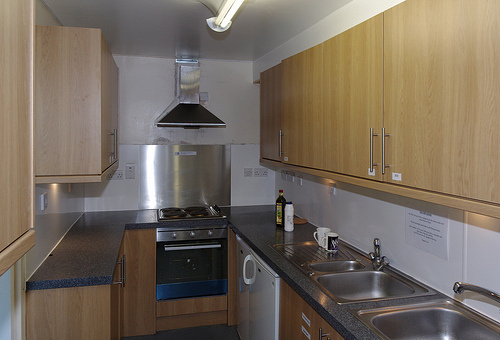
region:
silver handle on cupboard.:
[379, 127, 391, 172]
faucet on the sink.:
[348, 249, 390, 282]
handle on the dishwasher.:
[242, 253, 253, 284]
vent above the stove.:
[154, 101, 221, 138]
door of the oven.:
[163, 242, 223, 277]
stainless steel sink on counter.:
[342, 273, 384, 297]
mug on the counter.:
[312, 231, 340, 248]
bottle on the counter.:
[269, 188, 286, 228]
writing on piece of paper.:
[403, 211, 443, 251]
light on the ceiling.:
[212, 7, 251, 28]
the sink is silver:
[274, 167, 414, 336]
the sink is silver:
[215, 107, 375, 315]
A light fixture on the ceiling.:
[200, 0, 252, 36]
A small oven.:
[150, 225, 230, 300]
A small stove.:
[150, 195, 230, 225]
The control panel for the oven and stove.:
[155, 220, 235, 240]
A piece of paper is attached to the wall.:
[387, 192, 457, 267]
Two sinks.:
[317, 262, 464, 334]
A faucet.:
[436, 271, 496, 321]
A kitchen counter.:
[32, 205, 152, 307]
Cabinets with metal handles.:
[252, 0, 497, 210]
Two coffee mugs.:
[305, 218, 347, 256]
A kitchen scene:
[14, 28, 484, 326]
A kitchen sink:
[288, 262, 496, 339]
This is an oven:
[151, 222, 231, 304]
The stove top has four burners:
[154, 197, 231, 227]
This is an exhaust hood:
[154, 60, 226, 144]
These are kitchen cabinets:
[254, 25, 494, 182]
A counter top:
[42, 217, 131, 294]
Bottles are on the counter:
[266, 185, 305, 242]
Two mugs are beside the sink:
[306, 222, 378, 273]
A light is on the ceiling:
[199, 0, 256, 41]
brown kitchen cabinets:
[278, 43, 444, 188]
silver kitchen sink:
[312, 236, 448, 338]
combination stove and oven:
[148, 156, 289, 258]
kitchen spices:
[253, 170, 313, 232]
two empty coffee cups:
[303, 214, 354, 279]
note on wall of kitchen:
[376, 205, 467, 263]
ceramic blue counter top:
[55, 205, 101, 275]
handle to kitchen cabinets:
[355, 111, 400, 166]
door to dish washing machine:
[228, 252, 263, 323]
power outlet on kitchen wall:
[119, 162, 146, 179]